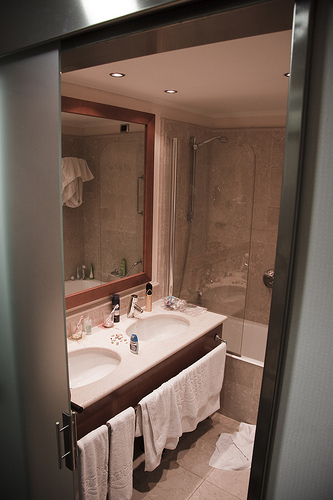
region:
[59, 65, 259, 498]
Doorway view of a bathroom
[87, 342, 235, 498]
Bathroom towels are white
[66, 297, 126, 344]
Toothbrushes are on the bathroom sink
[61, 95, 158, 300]
Large mirror in wooden frame is in the bathroom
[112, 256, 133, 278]
Body wash is in the mirror's reflection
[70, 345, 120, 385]
Bathroom sink is white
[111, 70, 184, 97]
small lights are on the ceiling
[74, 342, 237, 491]
Bathroom towels are hanging over a bar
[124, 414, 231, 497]
Bathroom towels are casting a shadow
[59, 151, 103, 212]
A white towel is in the mirror's reflection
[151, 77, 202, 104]
round light in the ceiling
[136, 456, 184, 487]
shadow on the floor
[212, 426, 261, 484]
white napkin on the floor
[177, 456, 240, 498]
tan tiles on the floor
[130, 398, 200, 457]
white towel on the rack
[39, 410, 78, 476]
silver door opener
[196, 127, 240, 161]
long silver shower head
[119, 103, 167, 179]
brown edge of the mirror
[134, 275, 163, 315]
brown and tan aerosol can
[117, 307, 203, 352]
large round sink in bathroom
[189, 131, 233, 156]
shower handle in the bathroom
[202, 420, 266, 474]
wet white towel on the bathroom floor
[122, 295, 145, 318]
bathroom sink faucet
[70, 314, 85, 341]
toothbrush holder next to the sink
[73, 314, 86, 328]
pink toothbrush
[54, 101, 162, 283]
bathroom mirrior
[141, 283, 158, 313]
soap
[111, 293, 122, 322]
shaving cream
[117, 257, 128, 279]
green shampoo bottle in the mirror reflection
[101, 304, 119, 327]
white toothbrush in a toothbrush holder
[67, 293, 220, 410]
Double bathroom sinks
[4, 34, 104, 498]
Sliding glass bathroom door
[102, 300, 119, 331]
White toothbrush in glass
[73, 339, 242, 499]
White towels hanging on sink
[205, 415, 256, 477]
White towel on bathroom floor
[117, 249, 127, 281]
Green bottle of shampoo reflected in mirror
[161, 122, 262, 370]
Glass shower shield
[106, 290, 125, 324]
Black canister on sink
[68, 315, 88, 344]
Pink and white toothbrush in glass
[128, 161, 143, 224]
Chrome shower bar reflected in mirror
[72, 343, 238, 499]
White towels hanging on the bar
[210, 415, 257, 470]
White towel on the floor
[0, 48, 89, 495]
Glass door in the bathroom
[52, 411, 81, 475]
Metal door handle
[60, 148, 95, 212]
White towel in the mirror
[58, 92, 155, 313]
Brown framed mirror in the bathroom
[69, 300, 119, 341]
Toothbrushes on the counter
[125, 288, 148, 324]
Silver faucet over the sink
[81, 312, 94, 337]
Hand soap on the counter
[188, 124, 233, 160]
Silver showerhead over the bathtub